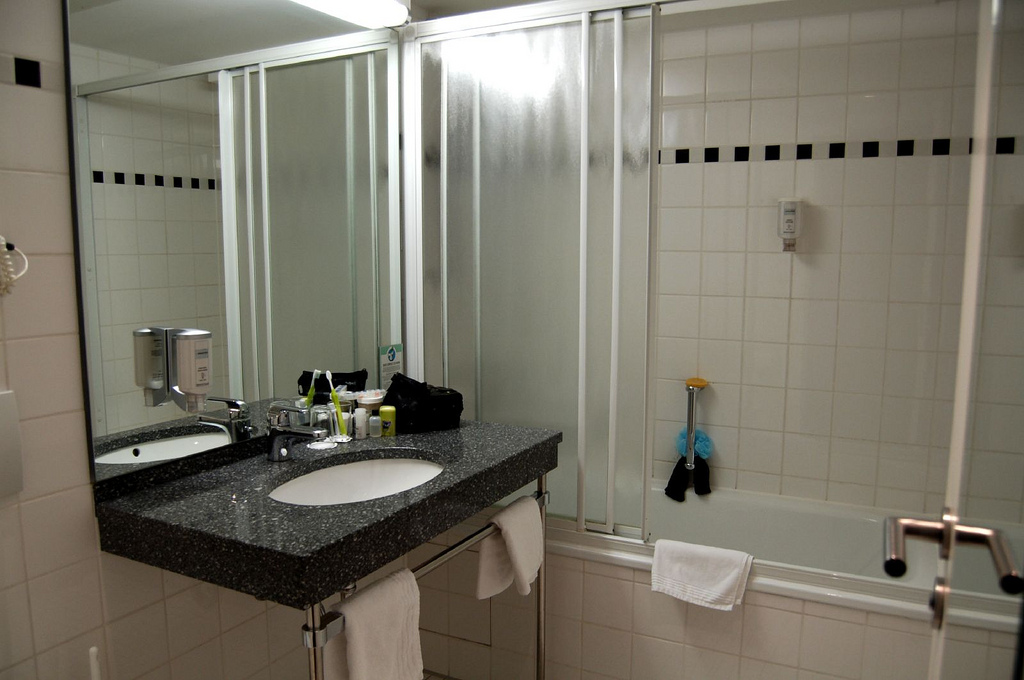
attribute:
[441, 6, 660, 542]
sliding doors — clear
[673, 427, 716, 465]
puff — blue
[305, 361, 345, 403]
toothbrush — yellow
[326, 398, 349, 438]
cup — clear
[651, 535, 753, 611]
cloth — white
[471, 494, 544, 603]
cloth — white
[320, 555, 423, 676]
cloth — white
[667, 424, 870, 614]
bathtub — white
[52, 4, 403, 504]
mirror — above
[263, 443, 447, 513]
sink bowl — on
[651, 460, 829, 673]
towel — hanging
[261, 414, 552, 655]
tub — bath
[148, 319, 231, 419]
dispenser — white, silver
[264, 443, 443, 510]
sink — white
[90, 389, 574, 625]
counter — black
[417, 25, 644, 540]
doors — clear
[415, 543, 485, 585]
bar — silver